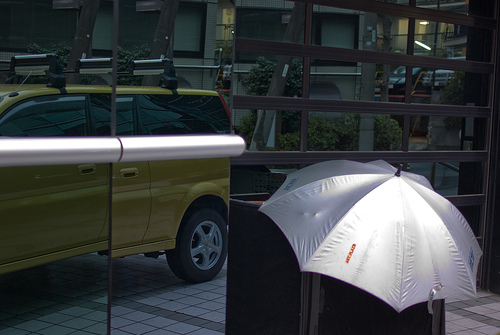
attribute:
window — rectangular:
[233, 5, 360, 65]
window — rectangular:
[306, 56, 406, 104]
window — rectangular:
[408, 62, 491, 109]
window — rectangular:
[406, 110, 488, 152]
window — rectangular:
[304, 108, 402, 153]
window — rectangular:
[309, 3, 408, 55]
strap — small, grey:
[426, 282, 445, 317]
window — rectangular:
[414, 68, 471, 101]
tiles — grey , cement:
[3, 254, 230, 334]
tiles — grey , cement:
[447, 290, 499, 330]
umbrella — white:
[260, 146, 485, 313]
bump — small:
[299, 204, 327, 224]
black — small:
[399, 168, 403, 172]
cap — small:
[394, 160, 404, 175]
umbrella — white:
[249, 156, 497, 321]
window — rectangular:
[309, 109, 407, 149]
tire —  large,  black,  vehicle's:
[170, 207, 225, 277]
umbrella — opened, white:
[256, 154, 418, 274]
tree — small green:
[235, 17, 345, 132]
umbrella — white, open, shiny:
[256, 158, 483, 312]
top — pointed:
[393, 163, 404, 177]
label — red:
[343, 239, 359, 269]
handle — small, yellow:
[118, 164, 138, 179]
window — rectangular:
[406, 110, 476, 148]